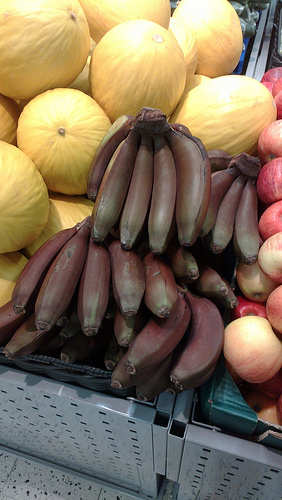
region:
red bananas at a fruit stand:
[53, 104, 217, 346]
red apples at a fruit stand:
[238, 117, 280, 386]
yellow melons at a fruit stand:
[4, 8, 109, 201]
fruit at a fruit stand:
[2, 5, 280, 438]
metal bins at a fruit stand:
[11, 376, 266, 492]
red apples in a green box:
[229, 278, 278, 477]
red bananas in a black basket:
[34, 275, 138, 393]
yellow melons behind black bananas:
[49, 58, 169, 192]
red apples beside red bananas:
[170, 255, 267, 331]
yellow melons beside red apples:
[231, 83, 280, 158]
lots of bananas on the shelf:
[77, 108, 230, 446]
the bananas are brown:
[74, 120, 216, 356]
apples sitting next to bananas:
[227, 159, 280, 325]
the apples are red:
[225, 298, 279, 392]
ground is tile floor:
[5, 457, 109, 498]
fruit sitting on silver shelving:
[4, 376, 278, 492]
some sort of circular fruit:
[47, 32, 266, 147]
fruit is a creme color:
[48, 15, 231, 107]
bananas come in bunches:
[72, 102, 232, 231]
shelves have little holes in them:
[36, 386, 120, 498]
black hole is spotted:
[176, 425, 181, 437]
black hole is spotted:
[174, 422, 182, 437]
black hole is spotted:
[175, 424, 180, 441]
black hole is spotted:
[176, 421, 179, 437]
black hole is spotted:
[178, 427, 181, 433]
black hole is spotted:
[176, 427, 180, 434]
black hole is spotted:
[173, 425, 177, 435]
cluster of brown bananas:
[85, 103, 213, 256]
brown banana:
[167, 120, 212, 249]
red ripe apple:
[257, 157, 280, 204]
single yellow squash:
[89, 15, 187, 114]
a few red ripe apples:
[236, 264, 280, 420]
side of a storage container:
[2, 374, 185, 490]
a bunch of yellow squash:
[2, 1, 244, 106]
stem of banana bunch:
[132, 107, 172, 128]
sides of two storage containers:
[245, 1, 276, 77]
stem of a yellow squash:
[51, 121, 71, 140]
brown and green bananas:
[81, 118, 219, 242]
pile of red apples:
[239, 270, 278, 361]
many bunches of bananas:
[81, 130, 255, 380]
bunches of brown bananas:
[85, 117, 220, 349]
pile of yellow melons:
[0, 12, 184, 86]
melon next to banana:
[14, 91, 213, 224]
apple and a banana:
[170, 302, 279, 364]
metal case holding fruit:
[15, 380, 132, 481]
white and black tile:
[7, 462, 67, 494]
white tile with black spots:
[15, 466, 79, 498]